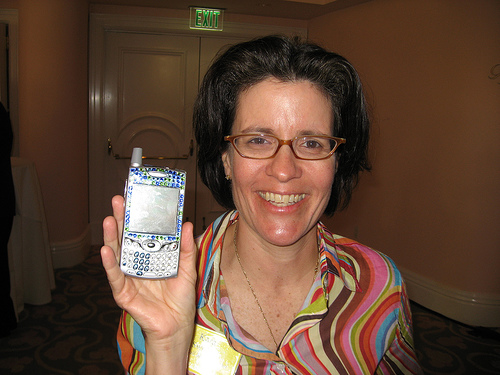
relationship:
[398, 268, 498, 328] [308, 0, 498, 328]
paneling on bottom of wall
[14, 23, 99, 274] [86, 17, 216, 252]
pillar next door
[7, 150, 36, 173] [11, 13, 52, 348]
knob on door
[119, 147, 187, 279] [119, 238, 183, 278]
cell phone has buttons